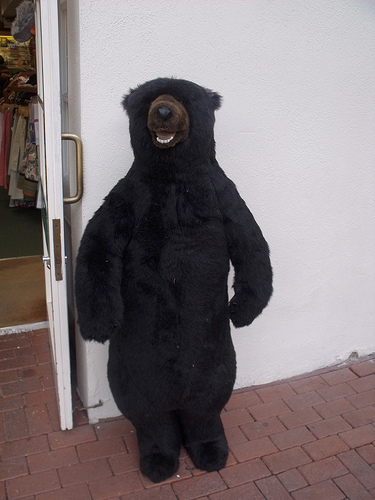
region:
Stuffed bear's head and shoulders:
[72, 75, 277, 312]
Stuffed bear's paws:
[56, 294, 276, 337]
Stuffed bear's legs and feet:
[112, 393, 242, 483]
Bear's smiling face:
[121, 74, 227, 169]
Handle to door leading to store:
[55, 128, 80, 204]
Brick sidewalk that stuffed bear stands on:
[235, 390, 370, 491]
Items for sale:
[0, 0, 40, 210]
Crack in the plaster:
[336, 348, 367, 363]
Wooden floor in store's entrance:
[1, 261, 43, 317]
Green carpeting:
[2, 210, 41, 251]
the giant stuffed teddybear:
[53, 39, 280, 497]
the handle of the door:
[57, 130, 84, 202]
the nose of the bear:
[156, 105, 171, 117]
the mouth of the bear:
[150, 124, 183, 148]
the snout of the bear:
[147, 88, 192, 149]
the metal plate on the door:
[51, 215, 64, 287]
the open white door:
[29, 0, 71, 429]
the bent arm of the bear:
[218, 191, 278, 330]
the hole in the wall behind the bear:
[342, 348, 365, 366]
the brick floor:
[0, 325, 373, 498]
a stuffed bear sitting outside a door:
[55, 73, 293, 498]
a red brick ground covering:
[251, 397, 355, 483]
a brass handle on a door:
[48, 123, 95, 239]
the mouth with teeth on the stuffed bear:
[146, 123, 178, 147]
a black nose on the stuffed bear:
[156, 105, 173, 121]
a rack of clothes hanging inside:
[6, 67, 47, 214]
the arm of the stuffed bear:
[194, 182, 307, 352]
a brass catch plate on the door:
[43, 213, 69, 286]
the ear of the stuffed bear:
[199, 78, 232, 124]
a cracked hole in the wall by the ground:
[336, 341, 369, 376]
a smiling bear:
[117, 76, 220, 163]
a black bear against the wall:
[78, 71, 269, 401]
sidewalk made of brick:
[232, 358, 372, 489]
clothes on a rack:
[1, 80, 42, 223]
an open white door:
[27, 3, 87, 356]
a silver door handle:
[55, 125, 89, 210]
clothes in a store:
[0, 70, 58, 243]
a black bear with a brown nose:
[111, 76, 235, 160]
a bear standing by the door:
[31, 58, 274, 385]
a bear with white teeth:
[114, 75, 231, 165]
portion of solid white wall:
[272, 15, 351, 339]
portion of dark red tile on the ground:
[257, 415, 373, 449]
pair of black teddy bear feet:
[131, 428, 239, 479]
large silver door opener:
[53, 125, 93, 206]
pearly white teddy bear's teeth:
[144, 126, 188, 154]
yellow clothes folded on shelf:
[0, 34, 32, 62]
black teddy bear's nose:
[145, 95, 187, 130]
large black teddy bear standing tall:
[77, 54, 317, 479]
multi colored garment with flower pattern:
[15, 114, 49, 222]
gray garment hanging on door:
[12, 1, 39, 48]